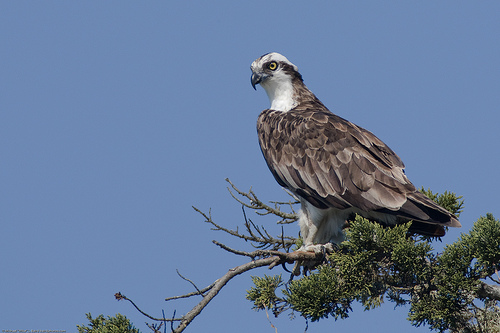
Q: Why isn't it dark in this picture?
A: It's daytime.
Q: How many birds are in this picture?
A: 1.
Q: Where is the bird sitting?
A: Branch.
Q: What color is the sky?
A: Blue.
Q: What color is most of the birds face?
A: White.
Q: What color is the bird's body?
A: Brown.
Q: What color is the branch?
A: Gray.